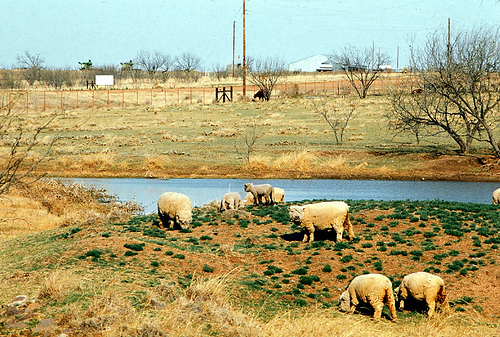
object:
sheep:
[244, 182, 277, 206]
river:
[32, 174, 500, 216]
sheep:
[156, 191, 194, 231]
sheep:
[337, 272, 399, 324]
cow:
[253, 89, 271, 103]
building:
[287, 52, 368, 74]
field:
[0, 72, 500, 185]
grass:
[169, 237, 178, 242]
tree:
[309, 97, 364, 145]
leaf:
[349, 144, 360, 150]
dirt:
[0, 198, 500, 336]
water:
[19, 175, 500, 215]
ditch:
[72, 197, 224, 226]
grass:
[317, 299, 331, 308]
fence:
[215, 85, 234, 104]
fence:
[0, 76, 437, 113]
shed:
[95, 74, 116, 90]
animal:
[253, 89, 271, 102]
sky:
[0, 1, 499, 72]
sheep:
[391, 271, 452, 319]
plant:
[430, 216, 437, 220]